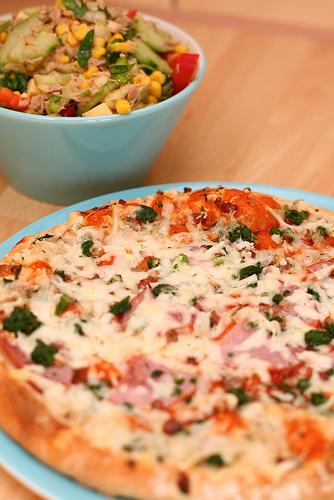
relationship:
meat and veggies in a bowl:
[5, 4, 178, 98] [14, 105, 191, 184]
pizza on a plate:
[67, 196, 288, 368] [118, 177, 190, 198]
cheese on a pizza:
[129, 273, 226, 347] [67, 196, 288, 368]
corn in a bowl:
[51, 19, 89, 49] [14, 105, 191, 184]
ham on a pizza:
[123, 352, 181, 402] [67, 196, 288, 368]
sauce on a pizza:
[227, 191, 280, 249] [67, 196, 288, 368]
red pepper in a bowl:
[171, 50, 206, 94] [14, 105, 191, 184]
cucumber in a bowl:
[2, 17, 57, 60] [14, 105, 191, 184]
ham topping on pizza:
[123, 352, 181, 402] [67, 196, 288, 368]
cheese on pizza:
[129, 273, 226, 347] [67, 196, 288, 368]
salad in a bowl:
[5, 4, 178, 98] [14, 105, 191, 184]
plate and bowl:
[118, 177, 190, 198] [14, 105, 191, 184]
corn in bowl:
[51, 19, 89, 49] [14, 105, 191, 184]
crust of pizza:
[21, 389, 90, 472] [67, 196, 288, 368]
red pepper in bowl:
[171, 50, 197, 92] [14, 105, 191, 184]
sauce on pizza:
[227, 191, 280, 249] [67, 196, 288, 368]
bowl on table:
[14, 105, 191, 184] [220, 3, 330, 156]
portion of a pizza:
[88, 203, 246, 268] [67, 196, 288, 368]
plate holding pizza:
[118, 177, 190, 198] [67, 196, 288, 368]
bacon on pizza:
[244, 336, 299, 389] [67, 196, 288, 368]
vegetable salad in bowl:
[59, 26, 153, 107] [14, 105, 191, 184]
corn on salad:
[51, 19, 89, 49] [28, 56, 126, 108]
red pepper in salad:
[171, 50, 197, 92] [28, 56, 126, 108]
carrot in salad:
[147, 20, 174, 54] [28, 56, 126, 108]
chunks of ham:
[213, 309, 286, 404] [123, 352, 181, 402]